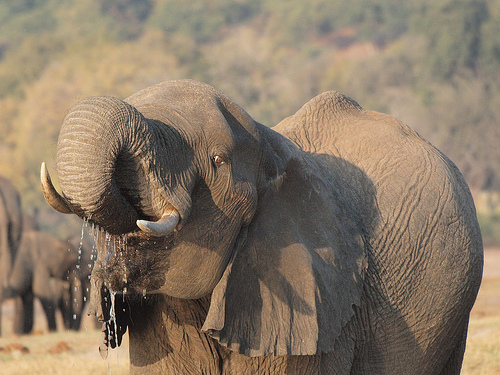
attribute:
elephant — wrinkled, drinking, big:
[67, 69, 487, 374]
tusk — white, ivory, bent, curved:
[133, 210, 189, 237]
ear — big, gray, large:
[240, 163, 376, 362]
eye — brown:
[207, 150, 228, 171]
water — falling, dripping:
[76, 235, 135, 297]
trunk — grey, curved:
[54, 91, 179, 199]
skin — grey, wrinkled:
[294, 87, 485, 304]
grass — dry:
[39, 359, 59, 369]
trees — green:
[127, 6, 228, 39]